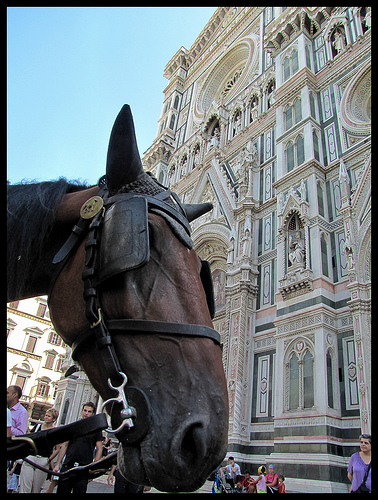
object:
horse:
[4, 97, 247, 493]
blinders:
[95, 192, 153, 278]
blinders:
[196, 255, 223, 322]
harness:
[8, 164, 239, 495]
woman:
[339, 431, 377, 495]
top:
[344, 451, 373, 493]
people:
[52, 395, 108, 494]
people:
[20, 404, 62, 495]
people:
[6, 381, 35, 496]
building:
[45, 8, 370, 495]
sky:
[5, 8, 219, 193]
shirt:
[10, 400, 29, 438]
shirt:
[60, 419, 108, 468]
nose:
[172, 417, 232, 483]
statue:
[285, 215, 309, 273]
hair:
[358, 433, 371, 447]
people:
[273, 474, 287, 494]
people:
[266, 462, 280, 495]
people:
[247, 464, 268, 497]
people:
[237, 468, 255, 495]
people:
[216, 452, 245, 496]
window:
[188, 36, 263, 116]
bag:
[351, 459, 372, 496]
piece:
[79, 195, 107, 219]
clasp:
[95, 369, 141, 436]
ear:
[181, 192, 217, 222]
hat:
[258, 465, 267, 474]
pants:
[15, 450, 53, 499]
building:
[2, 287, 75, 433]